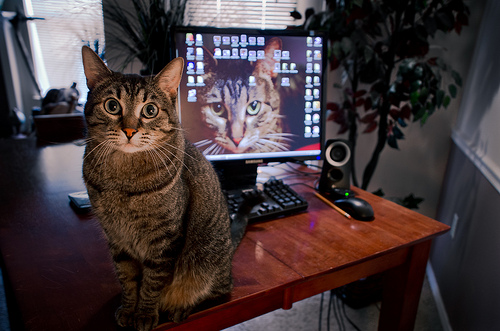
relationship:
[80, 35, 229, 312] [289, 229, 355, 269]
cat on desk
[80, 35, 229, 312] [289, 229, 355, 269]
cat sitting on desk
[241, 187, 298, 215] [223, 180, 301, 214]
black computer keyboard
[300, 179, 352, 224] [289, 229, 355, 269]
pencil on desk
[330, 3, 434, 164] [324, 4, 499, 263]
indoor tree in corner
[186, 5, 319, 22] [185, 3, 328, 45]
window with mini blinds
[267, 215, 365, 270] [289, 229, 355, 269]
brown table desk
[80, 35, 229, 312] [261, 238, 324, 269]
cat on table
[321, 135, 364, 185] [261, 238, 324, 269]
black speaker on table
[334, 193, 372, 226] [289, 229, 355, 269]
black mouse on table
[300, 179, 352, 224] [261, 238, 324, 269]
pencil on table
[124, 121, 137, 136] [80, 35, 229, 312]
orange nose of kitten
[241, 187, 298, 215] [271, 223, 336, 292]
black keyboard on table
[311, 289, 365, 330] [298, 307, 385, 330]
black wires on floor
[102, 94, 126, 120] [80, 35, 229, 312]
cat's eyes of a kitten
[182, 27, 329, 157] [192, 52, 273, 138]
monitor with cat wallpaper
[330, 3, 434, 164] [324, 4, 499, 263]
tree in corner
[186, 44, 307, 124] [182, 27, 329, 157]
icons on screen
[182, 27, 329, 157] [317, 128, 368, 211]
black computer speaker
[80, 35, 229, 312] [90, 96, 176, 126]
cat's very big eyes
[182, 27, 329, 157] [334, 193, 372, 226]
black computer mouse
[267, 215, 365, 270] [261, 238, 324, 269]
brown smooth wooden table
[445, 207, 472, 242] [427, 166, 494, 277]
electrical outlet on wall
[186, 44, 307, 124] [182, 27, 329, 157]
picture of cat on monitor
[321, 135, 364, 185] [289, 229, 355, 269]
black speaker on desk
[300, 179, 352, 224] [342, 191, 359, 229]
pencil next to mouse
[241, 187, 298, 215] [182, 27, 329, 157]
black keyboard below monitor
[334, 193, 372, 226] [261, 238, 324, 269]
black mouse on table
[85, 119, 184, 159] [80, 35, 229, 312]
white whiskers on cat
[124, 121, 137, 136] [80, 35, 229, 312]
orange nose on cat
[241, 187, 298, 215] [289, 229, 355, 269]
black keyboard on desk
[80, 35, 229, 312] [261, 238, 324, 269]
cat sitting on table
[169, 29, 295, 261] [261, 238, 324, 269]
computer monitor on table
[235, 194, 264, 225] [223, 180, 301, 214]
tail on keyboard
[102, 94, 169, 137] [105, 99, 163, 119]
cat's eyes are large and round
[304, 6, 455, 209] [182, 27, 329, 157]
plant between monitor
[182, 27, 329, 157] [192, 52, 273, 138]
cat as wallpaper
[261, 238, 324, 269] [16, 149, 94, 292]
table in shadow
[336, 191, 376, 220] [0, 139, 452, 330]
mouse on table